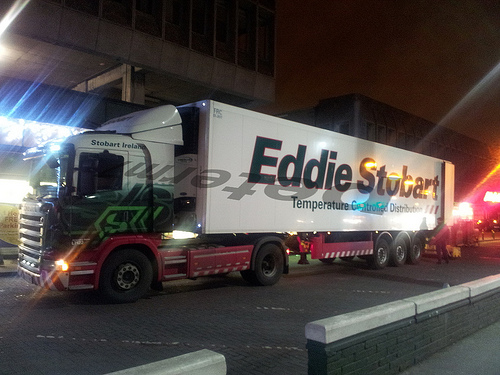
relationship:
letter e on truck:
[246, 135, 287, 186] [31, 97, 471, 289]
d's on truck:
[282, 146, 326, 197] [31, 97, 471, 289]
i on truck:
[323, 147, 339, 192] [31, 97, 471, 289]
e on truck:
[332, 162, 357, 197] [31, 97, 471, 289]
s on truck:
[350, 155, 383, 192] [31, 97, 471, 289]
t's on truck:
[373, 171, 452, 198] [31, 97, 471, 289]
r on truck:
[423, 174, 433, 201] [31, 97, 471, 289]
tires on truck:
[76, 231, 448, 296] [31, 97, 471, 289]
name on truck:
[228, 129, 459, 219] [31, 97, 471, 289]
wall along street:
[312, 278, 469, 374] [128, 251, 497, 350]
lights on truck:
[49, 258, 74, 274] [31, 97, 471, 289]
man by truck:
[427, 217, 452, 265] [31, 97, 471, 289]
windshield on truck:
[23, 140, 74, 194] [31, 97, 471, 289]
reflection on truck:
[60, 153, 409, 220] [31, 97, 471, 289]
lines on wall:
[405, 276, 490, 327] [312, 278, 469, 374]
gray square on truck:
[419, 202, 431, 217] [31, 97, 471, 289]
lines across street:
[15, 275, 310, 360] [128, 251, 497, 350]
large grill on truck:
[12, 186, 49, 286] [31, 97, 471, 289]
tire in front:
[96, 244, 154, 302] [0, 130, 172, 309]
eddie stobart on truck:
[228, 129, 459, 219] [31, 97, 471, 289]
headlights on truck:
[0, 187, 65, 220] [31, 97, 471, 289]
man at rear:
[427, 217, 452, 265] [403, 153, 472, 272]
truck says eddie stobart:
[31, 97, 471, 289] [228, 129, 459, 219]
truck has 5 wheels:
[31, 97, 471, 289] [76, 231, 448, 296]